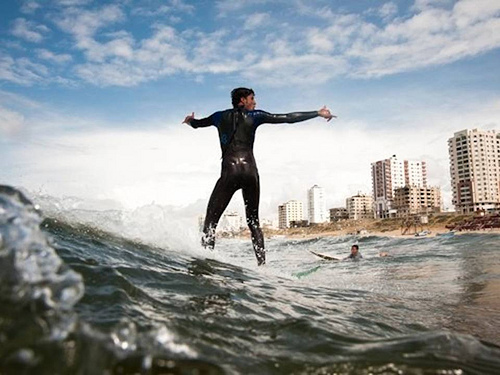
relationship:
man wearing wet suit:
[179, 84, 345, 262] [214, 111, 262, 197]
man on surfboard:
[346, 244, 393, 262] [308, 245, 341, 265]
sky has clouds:
[0, 3, 191, 111] [362, 22, 448, 71]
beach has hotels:
[293, 213, 465, 239] [282, 127, 496, 215]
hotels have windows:
[282, 127, 496, 215] [456, 142, 468, 151]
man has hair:
[179, 84, 345, 262] [229, 86, 255, 101]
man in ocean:
[179, 84, 345, 262] [2, 268, 498, 373]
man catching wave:
[179, 84, 345, 262] [3, 200, 187, 277]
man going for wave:
[346, 244, 393, 262] [3, 200, 187, 277]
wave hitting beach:
[3, 200, 187, 277] [293, 213, 465, 239]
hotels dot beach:
[282, 127, 496, 215] [293, 213, 465, 239]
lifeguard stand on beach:
[411, 212, 434, 234] [293, 213, 465, 239]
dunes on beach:
[303, 219, 364, 233] [293, 213, 465, 239]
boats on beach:
[416, 227, 432, 240] [293, 213, 465, 239]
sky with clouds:
[0, 3, 191, 111] [362, 22, 448, 71]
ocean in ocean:
[2, 268, 498, 373] [2, 236, 499, 373]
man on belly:
[346, 244, 393, 262] [357, 256, 370, 262]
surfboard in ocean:
[308, 245, 341, 265] [2, 268, 498, 373]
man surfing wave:
[179, 84, 345, 262] [3, 200, 187, 277]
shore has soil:
[289, 225, 487, 233] [355, 223, 366, 228]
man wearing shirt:
[346, 244, 393, 262] [353, 252, 362, 261]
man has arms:
[179, 84, 345, 262] [180, 107, 323, 131]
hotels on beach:
[282, 127, 496, 215] [293, 213, 465, 239]